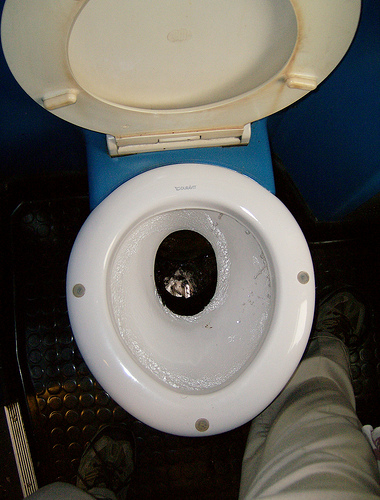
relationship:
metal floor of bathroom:
[34, 365, 82, 415] [3, 1, 362, 497]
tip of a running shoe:
[105, 424, 136, 443] [75, 423, 139, 499]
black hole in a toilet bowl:
[153, 225, 219, 317] [59, 161, 316, 442]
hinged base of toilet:
[107, 124, 252, 158] [1, 1, 360, 439]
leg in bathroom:
[257, 293, 369, 498] [3, 1, 362, 497]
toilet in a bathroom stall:
[77, 159, 280, 422] [5, 2, 375, 497]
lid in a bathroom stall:
[0, 0, 360, 157] [5, 2, 375, 497]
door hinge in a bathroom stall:
[4, 401, 37, 498] [5, 2, 375, 497]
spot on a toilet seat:
[292, 263, 322, 286] [1, 2, 368, 164]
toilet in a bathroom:
[77, 159, 280, 422] [16, 73, 361, 477]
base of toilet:
[147, 229, 226, 321] [62, 160, 326, 443]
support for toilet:
[86, 131, 277, 188] [62, 160, 326, 443]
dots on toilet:
[293, 270, 310, 287] [75, 187, 312, 409]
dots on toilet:
[193, 416, 209, 435] [75, 187, 312, 409]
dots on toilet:
[71, 283, 84, 299] [75, 187, 312, 409]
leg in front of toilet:
[257, 293, 369, 498] [44, 157, 334, 434]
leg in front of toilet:
[29, 416, 145, 497] [44, 157, 334, 434]